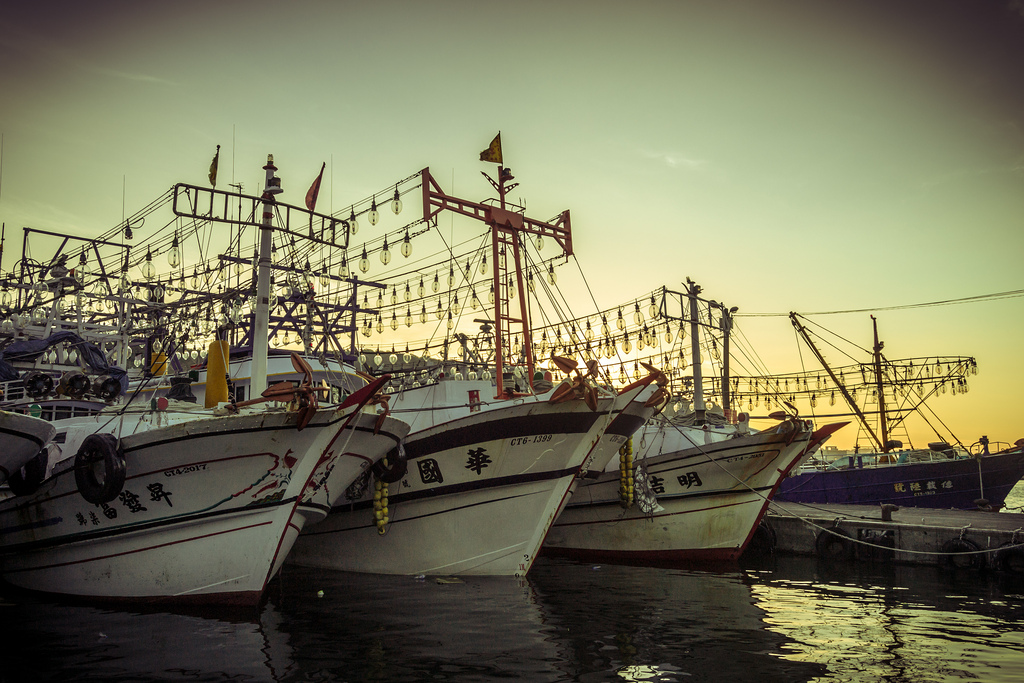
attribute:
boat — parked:
[332, 218, 665, 602]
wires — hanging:
[13, 120, 734, 428]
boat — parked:
[301, 361, 671, 597]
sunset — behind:
[509, 311, 978, 452]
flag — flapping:
[473, 124, 506, 167]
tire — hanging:
[1, 433, 50, 497]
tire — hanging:
[368, 437, 407, 480]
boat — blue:
[538, 212, 801, 564]